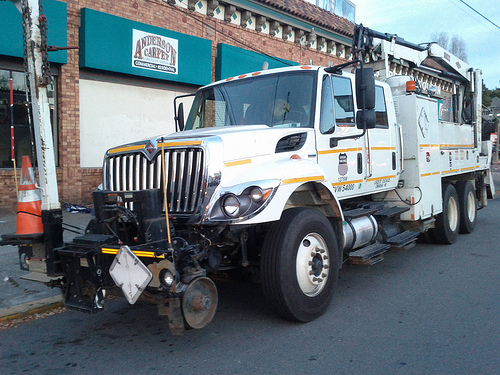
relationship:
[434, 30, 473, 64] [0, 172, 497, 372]
tree near street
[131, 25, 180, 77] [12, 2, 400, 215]
sign for business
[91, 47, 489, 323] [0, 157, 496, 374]
truck on road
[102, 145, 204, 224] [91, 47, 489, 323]
grill of truck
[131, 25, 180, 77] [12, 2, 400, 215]
logo of place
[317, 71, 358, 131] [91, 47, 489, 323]
window of truck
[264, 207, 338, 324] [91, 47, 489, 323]
wheel of truck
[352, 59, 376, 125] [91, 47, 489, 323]
mirror of truck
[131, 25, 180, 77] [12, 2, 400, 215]
sign on store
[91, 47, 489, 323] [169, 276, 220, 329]
truck with wheels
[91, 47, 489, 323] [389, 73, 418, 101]
truck with bucket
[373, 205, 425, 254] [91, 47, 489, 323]
steps on truck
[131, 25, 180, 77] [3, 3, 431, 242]
sign on store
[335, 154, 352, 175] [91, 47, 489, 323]
emblem on truck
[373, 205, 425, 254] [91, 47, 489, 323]
steps into truck